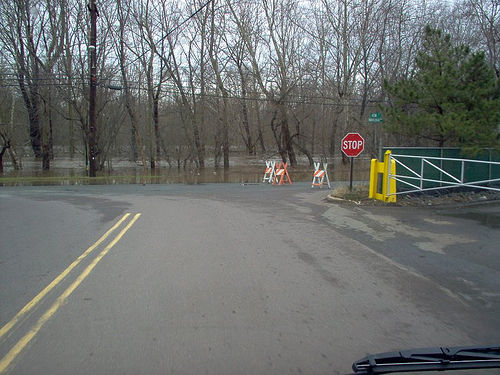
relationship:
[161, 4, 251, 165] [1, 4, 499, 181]
tree in woods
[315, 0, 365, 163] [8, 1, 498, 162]
tree in woods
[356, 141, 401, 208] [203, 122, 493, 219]
barrier near fence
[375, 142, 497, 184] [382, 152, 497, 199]
fence behind gate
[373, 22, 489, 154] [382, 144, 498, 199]
tree behind fence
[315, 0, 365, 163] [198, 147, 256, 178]
tree in field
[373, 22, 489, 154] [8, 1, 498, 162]
tree in woods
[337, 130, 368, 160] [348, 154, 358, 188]
sign on a pole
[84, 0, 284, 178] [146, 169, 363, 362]
trees by road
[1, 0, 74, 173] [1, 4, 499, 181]
tree in woods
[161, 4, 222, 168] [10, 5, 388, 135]
tree in woods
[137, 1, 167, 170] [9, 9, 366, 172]
tree in woods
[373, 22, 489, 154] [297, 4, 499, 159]
tree in woods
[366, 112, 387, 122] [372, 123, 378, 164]
sign on pole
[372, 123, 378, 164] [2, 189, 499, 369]
pole on street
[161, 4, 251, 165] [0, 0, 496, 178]
tree in field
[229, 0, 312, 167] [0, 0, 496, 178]
tree in field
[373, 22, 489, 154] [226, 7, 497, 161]
tree in field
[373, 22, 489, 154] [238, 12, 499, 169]
tree in field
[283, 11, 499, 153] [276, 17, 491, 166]
tree in field